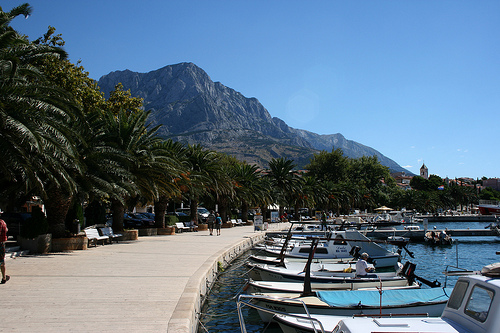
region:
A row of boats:
[228, 193, 463, 329]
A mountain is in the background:
[101, 58, 436, 221]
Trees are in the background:
[103, 131, 422, 212]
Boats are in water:
[209, 206, 476, 331]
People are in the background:
[178, 198, 228, 239]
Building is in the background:
[415, 158, 435, 185]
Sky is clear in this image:
[12, 4, 497, 93]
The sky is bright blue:
[37, 7, 494, 128]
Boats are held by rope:
[201, 246, 263, 328]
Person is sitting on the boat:
[346, 242, 382, 283]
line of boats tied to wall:
[251, 228, 458, 331]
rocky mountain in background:
[123, 52, 309, 149]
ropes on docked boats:
[204, 265, 243, 318]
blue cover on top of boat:
[311, 276, 451, 311]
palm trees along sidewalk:
[69, 104, 229, 240]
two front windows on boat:
[448, 277, 498, 319]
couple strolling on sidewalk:
[202, 206, 224, 239]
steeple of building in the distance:
[415, 159, 433, 182]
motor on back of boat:
[397, 261, 439, 287]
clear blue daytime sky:
[296, 16, 393, 69]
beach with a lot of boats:
[14, 15, 498, 327]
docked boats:
[238, 150, 439, 327]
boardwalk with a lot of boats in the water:
[209, 150, 464, 321]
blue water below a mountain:
[19, 14, 469, 287]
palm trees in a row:
[7, 31, 456, 226]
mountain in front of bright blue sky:
[99, 23, 472, 202]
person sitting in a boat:
[236, 240, 433, 287]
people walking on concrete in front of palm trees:
[138, 38, 279, 265]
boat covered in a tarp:
[223, 273, 474, 320]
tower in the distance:
[404, 150, 447, 201]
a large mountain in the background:
[80, 61, 444, 212]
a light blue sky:
[263, 26, 390, 71]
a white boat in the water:
[242, 253, 427, 283]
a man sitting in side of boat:
[357, 251, 380, 280]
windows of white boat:
[443, 276, 493, 326]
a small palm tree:
[3, 4, 80, 233]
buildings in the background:
[393, 160, 498, 192]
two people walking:
[204, 208, 223, 238]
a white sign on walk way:
[248, 215, 265, 231]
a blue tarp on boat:
[315, 284, 462, 306]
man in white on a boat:
[342, 242, 377, 289]